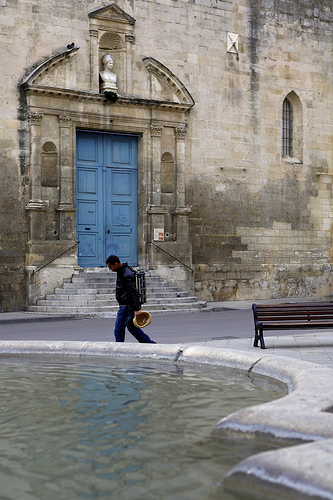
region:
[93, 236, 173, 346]
this is a person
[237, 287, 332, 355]
this is a chair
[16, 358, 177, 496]
this is a body of water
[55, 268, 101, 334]
this is a stair case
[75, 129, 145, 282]
this is a door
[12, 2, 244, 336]
this is a building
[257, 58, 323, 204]
this is a window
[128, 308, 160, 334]
this is a hat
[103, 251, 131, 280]
this is a head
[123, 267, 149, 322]
this is a hand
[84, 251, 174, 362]
this man is walking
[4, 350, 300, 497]
water in a fountain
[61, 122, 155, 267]
the door is blue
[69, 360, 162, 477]
the reflection of a door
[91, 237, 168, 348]
the man is wearing blue jeans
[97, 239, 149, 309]
he is wearing a dark blue jacket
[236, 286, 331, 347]
the bench is made of wood and iron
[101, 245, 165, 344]
a man walking around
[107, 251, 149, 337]
he is holding a hat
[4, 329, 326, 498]
a wishing well at the middle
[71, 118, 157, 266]
the big blue door at the church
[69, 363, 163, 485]
reflection of the blue door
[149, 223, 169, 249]
the signage is painted with red color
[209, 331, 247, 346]
a drainage at the side street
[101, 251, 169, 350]
man walking on the sidewalk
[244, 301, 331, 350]
empty bench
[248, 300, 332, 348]
brown and black bench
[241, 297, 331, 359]
bench on the sidewalk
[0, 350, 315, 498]
small body of water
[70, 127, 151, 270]
tall blue doors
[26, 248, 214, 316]
steps leading up to the door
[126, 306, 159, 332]
hat in the hand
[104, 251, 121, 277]
head is tilted down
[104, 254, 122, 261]
dark hair on the head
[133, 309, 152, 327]
A hat in the man's hand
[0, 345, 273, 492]
A pool of water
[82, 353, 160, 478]
A reflection on the water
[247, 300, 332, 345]
A wooden bench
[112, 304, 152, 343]
A pair of blue jeans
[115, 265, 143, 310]
A black jacket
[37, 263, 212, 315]
A set of stone stairs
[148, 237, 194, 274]
A railing by the stairs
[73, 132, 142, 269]
Large blue doors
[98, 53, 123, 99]
Statue above a door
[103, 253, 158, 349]
Man walking by a building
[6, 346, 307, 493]
Fountain filled with water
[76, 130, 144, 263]
Doors to a building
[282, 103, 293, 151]
Bars on a window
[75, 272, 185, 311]
Steps made of concrete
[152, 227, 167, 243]
Sign by the steps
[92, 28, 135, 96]
Decoration on a building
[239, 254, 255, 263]
A stone in a wall.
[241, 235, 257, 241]
A stone in a wall.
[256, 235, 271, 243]
A stone in a wall.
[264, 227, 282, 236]
A stone in a wall.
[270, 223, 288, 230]
A stone in a wall.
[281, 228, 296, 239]
A stone in a wall.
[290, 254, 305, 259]
A stone in a wall.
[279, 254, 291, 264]
A stone in a wall.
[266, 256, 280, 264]
A stone in a wall.